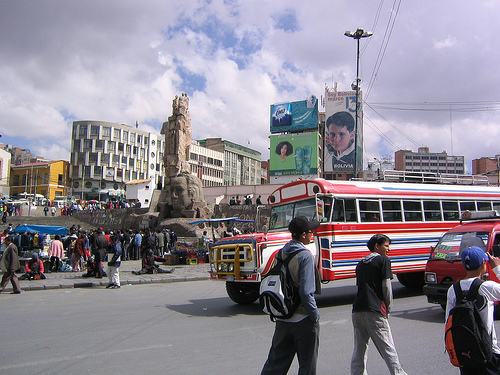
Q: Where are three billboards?
A: Above the bus.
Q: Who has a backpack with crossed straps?
A: Man in blue cap.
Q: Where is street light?
A: In front of billboards.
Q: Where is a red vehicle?
A: This side of bus.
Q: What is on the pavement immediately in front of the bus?
A: Shadow of bus.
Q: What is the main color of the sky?
A: Blue.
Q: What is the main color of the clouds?
A: White.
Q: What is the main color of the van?
A: Red.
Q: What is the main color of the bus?
A: Red.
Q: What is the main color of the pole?
A: Gray.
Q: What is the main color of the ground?
A: Gray.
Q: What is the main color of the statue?
A: Tan.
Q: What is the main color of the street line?
A: Gray.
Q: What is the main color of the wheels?
A: Black.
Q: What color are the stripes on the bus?
A: Red, white, and blue.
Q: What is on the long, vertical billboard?
A: A young man.